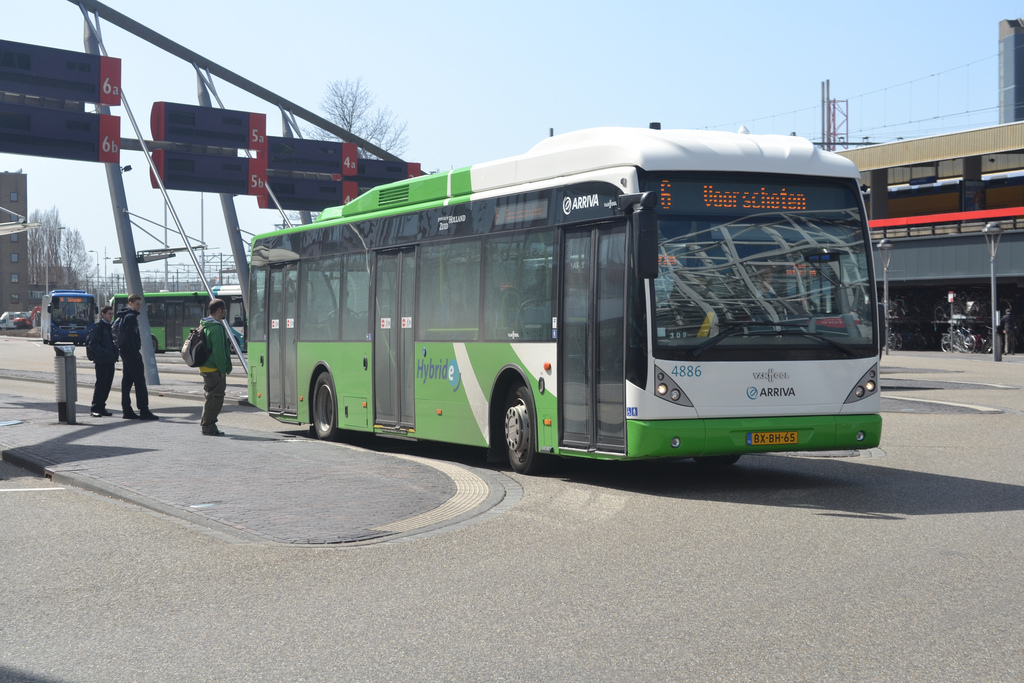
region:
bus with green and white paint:
[239, 130, 888, 476]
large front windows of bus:
[634, 127, 887, 454]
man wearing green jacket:
[178, 296, 237, 434]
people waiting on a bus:
[87, 292, 237, 433]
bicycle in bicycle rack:
[937, 323, 977, 356]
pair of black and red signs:
[147, 96, 274, 201]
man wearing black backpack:
[182, 296, 240, 436]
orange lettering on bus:
[241, 125, 890, 476]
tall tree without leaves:
[314, 77, 412, 163]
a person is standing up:
[167, 291, 241, 450]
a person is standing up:
[115, 297, 150, 425]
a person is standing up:
[81, 297, 124, 418]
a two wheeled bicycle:
[932, 311, 978, 362]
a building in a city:
[865, 134, 1018, 346]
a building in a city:
[6, 172, 35, 331]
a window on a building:
[5, 186, 32, 203]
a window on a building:
[5, 226, 28, 240]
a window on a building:
[5, 246, 13, 263]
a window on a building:
[11, 265, 22, 285]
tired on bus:
[483, 386, 551, 481]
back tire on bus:
[299, 370, 348, 444]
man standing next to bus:
[171, 306, 242, 437]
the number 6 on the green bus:
[654, 177, 687, 219]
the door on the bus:
[562, 230, 638, 446]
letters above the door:
[563, 183, 605, 221]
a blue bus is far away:
[31, 279, 92, 341]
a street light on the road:
[970, 221, 1022, 365]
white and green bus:
[215, 119, 911, 493]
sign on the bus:
[648, 158, 842, 247]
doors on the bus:
[543, 189, 660, 478]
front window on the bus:
[638, 199, 873, 361]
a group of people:
[70, 253, 255, 416]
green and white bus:
[213, 131, 957, 483]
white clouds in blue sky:
[903, 11, 961, 95]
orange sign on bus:
[653, 170, 806, 229]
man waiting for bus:
[167, 270, 259, 432]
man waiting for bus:
[80, 274, 180, 410]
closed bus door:
[555, 214, 639, 445]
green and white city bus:
[223, 146, 914, 510]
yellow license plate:
[738, 429, 805, 446]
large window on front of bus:
[646, 203, 880, 356]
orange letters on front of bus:
[648, 168, 819, 223]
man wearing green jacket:
[175, 291, 251, 431]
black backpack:
[177, 322, 212, 370]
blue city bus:
[35, 284, 100, 346]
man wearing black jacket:
[111, 285, 153, 429]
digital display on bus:
[637, 154, 881, 235]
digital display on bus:
[643, 157, 866, 237]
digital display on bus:
[637, 157, 869, 237]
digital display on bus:
[630, 155, 886, 238]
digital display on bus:
[637, 152, 882, 242]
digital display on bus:
[640, 149, 874, 235]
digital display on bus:
[627, 151, 875, 231]